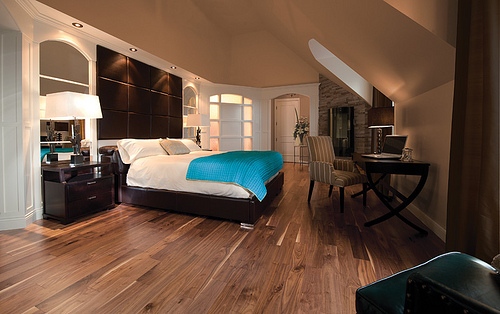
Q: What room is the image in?
A: It is at the bedroom.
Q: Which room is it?
A: It is a bedroom.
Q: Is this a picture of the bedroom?
A: Yes, it is showing the bedroom.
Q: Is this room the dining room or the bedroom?
A: It is the bedroom.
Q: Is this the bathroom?
A: No, it is the bedroom.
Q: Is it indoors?
A: Yes, it is indoors.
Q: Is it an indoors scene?
A: Yes, it is indoors.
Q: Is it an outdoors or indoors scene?
A: It is indoors.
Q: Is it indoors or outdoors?
A: It is indoors.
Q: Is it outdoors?
A: No, it is indoors.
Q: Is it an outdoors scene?
A: No, it is indoors.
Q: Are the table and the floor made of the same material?
A: Yes, both the table and the floor are made of wood.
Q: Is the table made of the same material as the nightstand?
A: Yes, both the table and the nightstand are made of wood.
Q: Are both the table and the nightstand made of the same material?
A: Yes, both the table and the nightstand are made of wood.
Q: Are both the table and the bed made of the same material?
A: Yes, both the table and the bed are made of wood.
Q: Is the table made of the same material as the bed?
A: Yes, both the table and the bed are made of wood.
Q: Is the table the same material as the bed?
A: Yes, both the table and the bed are made of wood.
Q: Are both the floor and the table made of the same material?
A: Yes, both the floor and the table are made of wood.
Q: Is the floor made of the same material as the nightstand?
A: Yes, both the floor and the nightstand are made of wood.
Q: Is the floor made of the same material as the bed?
A: Yes, both the floor and the bed are made of wood.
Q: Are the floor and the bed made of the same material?
A: Yes, both the floor and the bed are made of wood.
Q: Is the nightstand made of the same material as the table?
A: Yes, both the nightstand and the table are made of wood.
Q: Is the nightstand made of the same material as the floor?
A: Yes, both the nightstand and the floor are made of wood.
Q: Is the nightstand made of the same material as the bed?
A: Yes, both the nightstand and the bed are made of wood.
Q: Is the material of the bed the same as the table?
A: Yes, both the bed and the table are made of wood.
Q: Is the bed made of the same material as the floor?
A: Yes, both the bed and the floor are made of wood.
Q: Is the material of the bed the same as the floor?
A: Yes, both the bed and the floor are made of wood.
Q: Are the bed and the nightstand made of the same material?
A: Yes, both the bed and the nightstand are made of wood.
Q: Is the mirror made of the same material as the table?
A: No, the mirror is made of glass and the table is made of wood.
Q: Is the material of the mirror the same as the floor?
A: No, the mirror is made of glass and the floor is made of wood.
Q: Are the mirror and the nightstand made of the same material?
A: No, the mirror is made of glass and the nightstand is made of wood.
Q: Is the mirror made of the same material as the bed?
A: No, the mirror is made of glass and the bed is made of wood.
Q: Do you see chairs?
A: Yes, there is a chair.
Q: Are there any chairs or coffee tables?
A: Yes, there is a chair.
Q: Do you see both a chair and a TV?
A: No, there is a chair but no televisions.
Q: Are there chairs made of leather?
A: Yes, there is a chair that is made of leather.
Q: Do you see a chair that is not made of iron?
A: Yes, there is a chair that is made of leather.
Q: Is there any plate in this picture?
A: No, there are no plates.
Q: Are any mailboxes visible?
A: No, there are no mailboxes.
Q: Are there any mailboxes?
A: No, there are no mailboxes.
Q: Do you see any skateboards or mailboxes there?
A: No, there are no mailboxes or skateboards.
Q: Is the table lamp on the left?
A: Yes, the table lamp is on the left of the image.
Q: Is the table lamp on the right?
A: No, the table lamp is on the left of the image.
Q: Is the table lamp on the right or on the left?
A: The table lamp is on the left of the image.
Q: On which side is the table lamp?
A: The table lamp is on the left of the image.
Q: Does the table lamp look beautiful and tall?
A: Yes, the table lamp is beautiful and tall.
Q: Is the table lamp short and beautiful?
A: No, the table lamp is beautiful but tall.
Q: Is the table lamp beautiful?
A: Yes, the table lamp is beautiful.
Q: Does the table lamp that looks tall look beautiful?
A: Yes, the table lamp is beautiful.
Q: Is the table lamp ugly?
A: No, the table lamp is beautiful.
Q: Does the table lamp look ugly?
A: No, the table lamp is beautiful.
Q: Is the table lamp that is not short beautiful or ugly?
A: The table lamp is beautiful.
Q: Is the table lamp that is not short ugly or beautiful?
A: The table lamp is beautiful.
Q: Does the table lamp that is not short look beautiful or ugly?
A: The table lamp is beautiful.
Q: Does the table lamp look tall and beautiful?
A: Yes, the table lamp is tall and beautiful.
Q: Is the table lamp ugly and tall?
A: No, the table lamp is tall but beautiful.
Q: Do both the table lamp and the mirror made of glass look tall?
A: Yes, both the table lamp and the mirror are tall.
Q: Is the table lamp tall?
A: Yes, the table lamp is tall.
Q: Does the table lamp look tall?
A: Yes, the table lamp is tall.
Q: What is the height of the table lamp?
A: The table lamp is tall.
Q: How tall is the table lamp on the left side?
A: The table lamp is tall.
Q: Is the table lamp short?
A: No, the table lamp is tall.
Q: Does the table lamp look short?
A: No, the table lamp is tall.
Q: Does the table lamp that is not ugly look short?
A: No, the table lamp is tall.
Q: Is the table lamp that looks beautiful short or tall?
A: The table lamp is tall.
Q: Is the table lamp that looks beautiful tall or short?
A: The table lamp is tall.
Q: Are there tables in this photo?
A: Yes, there is a table.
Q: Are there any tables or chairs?
A: Yes, there is a table.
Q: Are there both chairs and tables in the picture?
A: Yes, there are both a table and a chair.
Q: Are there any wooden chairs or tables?
A: Yes, there is a wood table.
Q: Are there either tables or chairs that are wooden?
A: Yes, the table is wooden.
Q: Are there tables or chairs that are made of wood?
A: Yes, the table is made of wood.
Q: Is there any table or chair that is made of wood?
A: Yes, the table is made of wood.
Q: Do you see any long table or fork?
A: Yes, there is a long table.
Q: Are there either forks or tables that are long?
A: Yes, the table is long.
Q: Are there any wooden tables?
A: Yes, there is a wood table.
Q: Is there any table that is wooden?
A: Yes, there is a table that is wooden.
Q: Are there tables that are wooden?
A: Yes, there is a table that is wooden.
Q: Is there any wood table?
A: Yes, there is a table that is made of wood.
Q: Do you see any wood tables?
A: Yes, there is a table that is made of wood.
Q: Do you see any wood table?
A: Yes, there is a table that is made of wood.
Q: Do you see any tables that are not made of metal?
A: Yes, there is a table that is made of wood.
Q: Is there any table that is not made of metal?
A: Yes, there is a table that is made of wood.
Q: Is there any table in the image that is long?
A: Yes, there is a table that is long.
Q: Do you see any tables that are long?
A: Yes, there is a table that is long.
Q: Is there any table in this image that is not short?
A: Yes, there is a long table.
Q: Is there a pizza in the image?
A: No, there are no pizzas.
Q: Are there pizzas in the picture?
A: No, there are no pizzas.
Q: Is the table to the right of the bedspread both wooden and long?
A: Yes, the table is wooden and long.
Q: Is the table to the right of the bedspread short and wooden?
A: No, the table is wooden but long.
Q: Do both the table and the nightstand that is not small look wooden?
A: Yes, both the table and the nightstand are wooden.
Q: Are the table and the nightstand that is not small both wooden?
A: Yes, both the table and the nightstand are wooden.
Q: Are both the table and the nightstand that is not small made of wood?
A: Yes, both the table and the nightstand are made of wood.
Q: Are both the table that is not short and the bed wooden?
A: Yes, both the table and the bed are wooden.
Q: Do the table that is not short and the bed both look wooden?
A: Yes, both the table and the bed are wooden.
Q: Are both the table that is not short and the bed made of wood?
A: Yes, both the table and the bed are made of wood.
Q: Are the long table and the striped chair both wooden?
A: Yes, both the table and the chair are wooden.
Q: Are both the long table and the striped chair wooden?
A: Yes, both the table and the chair are wooden.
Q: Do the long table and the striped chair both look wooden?
A: Yes, both the table and the chair are wooden.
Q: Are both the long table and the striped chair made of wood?
A: Yes, both the table and the chair are made of wood.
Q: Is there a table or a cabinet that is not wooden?
A: No, there is a table but it is wooden.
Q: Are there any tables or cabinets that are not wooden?
A: No, there is a table but it is wooden.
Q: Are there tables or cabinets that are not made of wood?
A: No, there is a table but it is made of wood.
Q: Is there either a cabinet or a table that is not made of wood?
A: No, there is a table but it is made of wood.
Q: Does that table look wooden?
A: Yes, the table is wooden.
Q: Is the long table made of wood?
A: Yes, the table is made of wood.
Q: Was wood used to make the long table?
A: Yes, the table is made of wood.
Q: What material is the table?
A: The table is made of wood.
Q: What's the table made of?
A: The table is made of wood.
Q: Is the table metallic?
A: No, the table is wooden.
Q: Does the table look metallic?
A: No, the table is wooden.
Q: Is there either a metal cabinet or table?
A: No, there is a table but it is wooden.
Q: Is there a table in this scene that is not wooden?
A: No, there is a table but it is wooden.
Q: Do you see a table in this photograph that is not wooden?
A: No, there is a table but it is wooden.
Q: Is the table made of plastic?
A: No, the table is made of wood.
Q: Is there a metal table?
A: No, there is a table but it is made of wood.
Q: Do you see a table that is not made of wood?
A: No, there is a table but it is made of wood.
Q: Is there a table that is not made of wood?
A: No, there is a table but it is made of wood.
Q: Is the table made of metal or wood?
A: The table is made of wood.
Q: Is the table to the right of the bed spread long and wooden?
A: Yes, the table is long and wooden.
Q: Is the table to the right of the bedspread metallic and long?
A: No, the table is long but wooden.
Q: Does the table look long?
A: Yes, the table is long.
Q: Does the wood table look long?
A: Yes, the table is long.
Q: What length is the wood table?
A: The table is long.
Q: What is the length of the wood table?
A: The table is long.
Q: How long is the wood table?
A: The table is long.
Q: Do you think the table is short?
A: No, the table is long.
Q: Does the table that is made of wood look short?
A: No, the table is long.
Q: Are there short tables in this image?
A: No, there is a table but it is long.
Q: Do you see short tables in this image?
A: No, there is a table but it is long.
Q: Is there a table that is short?
A: No, there is a table but it is long.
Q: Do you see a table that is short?
A: No, there is a table but it is long.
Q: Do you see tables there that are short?
A: No, there is a table but it is long.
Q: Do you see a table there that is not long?
A: No, there is a table but it is long.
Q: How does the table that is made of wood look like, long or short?
A: The table is long.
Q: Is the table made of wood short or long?
A: The table is long.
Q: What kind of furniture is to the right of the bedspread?
A: The piece of furniture is a table.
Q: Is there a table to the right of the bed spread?
A: Yes, there is a table to the right of the bed spread.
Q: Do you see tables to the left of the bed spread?
A: No, the table is to the right of the bed spread.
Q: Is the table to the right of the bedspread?
A: Yes, the table is to the right of the bedspread.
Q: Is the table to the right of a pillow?
A: No, the table is to the right of the bedspread.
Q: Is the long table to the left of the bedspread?
A: No, the table is to the right of the bedspread.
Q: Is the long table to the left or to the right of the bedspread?
A: The table is to the right of the bedspread.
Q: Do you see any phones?
A: No, there are no phones.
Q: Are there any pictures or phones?
A: No, there are no phones or pictures.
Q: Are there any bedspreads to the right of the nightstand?
A: Yes, there is a bedspread to the right of the nightstand.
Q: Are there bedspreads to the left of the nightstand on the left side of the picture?
A: No, the bedspread is to the right of the nightstand.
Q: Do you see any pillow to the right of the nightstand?
A: No, there is a bedspread to the right of the nightstand.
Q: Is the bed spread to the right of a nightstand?
A: Yes, the bed spread is to the right of a nightstand.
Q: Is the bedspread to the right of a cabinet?
A: No, the bedspread is to the right of a nightstand.